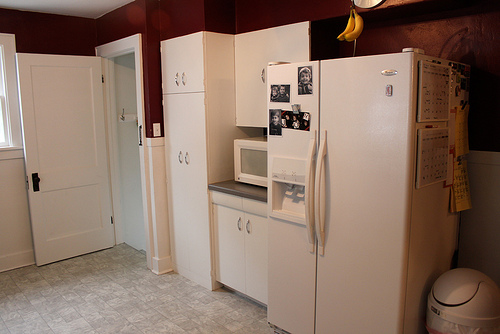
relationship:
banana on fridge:
[342, 5, 363, 42] [266, 46, 472, 334]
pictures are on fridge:
[298, 66, 314, 96] [260, 40, 469, 332]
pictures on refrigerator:
[264, 62, 314, 142] [257, 47, 482, 332]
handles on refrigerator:
[301, 122, 333, 256] [257, 47, 482, 332]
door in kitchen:
[8, 45, 122, 274] [4, 2, 498, 327]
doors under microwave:
[210, 198, 273, 308] [224, 133, 269, 189]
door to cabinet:
[223, 13, 273, 126] [224, 10, 336, 244]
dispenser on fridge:
[273, 178, 308, 219] [265, 30, 455, 330]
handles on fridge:
[276, 98, 352, 289] [232, 62, 448, 322]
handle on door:
[18, 126, 48, 170] [13, 49, 168, 294]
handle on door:
[32, 173, 41, 193] [13, 49, 168, 294]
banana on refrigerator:
[334, 16, 366, 62] [251, 30, 461, 312]